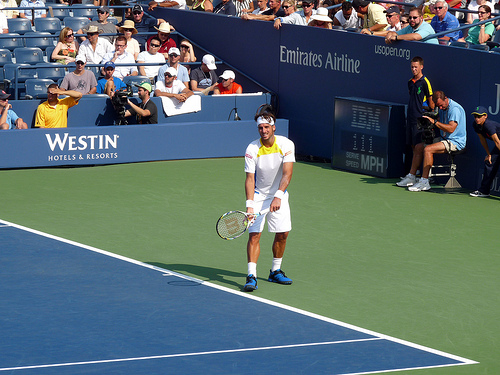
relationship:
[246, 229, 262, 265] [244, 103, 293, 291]
calves of calves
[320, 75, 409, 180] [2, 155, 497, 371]
tracker on tennis court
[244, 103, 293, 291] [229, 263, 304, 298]
calves wearing shoe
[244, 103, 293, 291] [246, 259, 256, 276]
calves wearing sock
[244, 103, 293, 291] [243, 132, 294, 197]
calves wearing white shirt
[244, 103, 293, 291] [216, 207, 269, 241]
calves holding racket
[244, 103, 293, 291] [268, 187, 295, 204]
calves wearing wristband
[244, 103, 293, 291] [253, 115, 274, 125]
calves wearing headband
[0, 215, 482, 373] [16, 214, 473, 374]
baseline on court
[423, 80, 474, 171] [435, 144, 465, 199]
man sitting in chair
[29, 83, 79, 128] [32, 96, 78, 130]
man wearing yellow shirt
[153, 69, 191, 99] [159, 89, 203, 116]
man leaning against towel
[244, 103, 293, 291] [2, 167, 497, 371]
calves on court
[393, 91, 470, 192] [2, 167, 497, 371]
man on court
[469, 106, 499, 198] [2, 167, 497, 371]
boy on court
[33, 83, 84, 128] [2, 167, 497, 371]
man on court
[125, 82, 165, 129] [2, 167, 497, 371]
person on court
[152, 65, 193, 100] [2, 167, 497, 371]
man on court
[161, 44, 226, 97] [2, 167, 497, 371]
person on court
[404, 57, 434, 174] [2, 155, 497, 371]
person on tennis court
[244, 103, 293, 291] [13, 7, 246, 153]
calves sitting in stands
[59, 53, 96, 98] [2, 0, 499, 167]
person sitting in stands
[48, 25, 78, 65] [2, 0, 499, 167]
person sitting in stands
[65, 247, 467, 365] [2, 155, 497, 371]
lines on tennis court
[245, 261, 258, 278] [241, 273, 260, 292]
sock inside shoe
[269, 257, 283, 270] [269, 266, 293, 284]
sock inside shoe